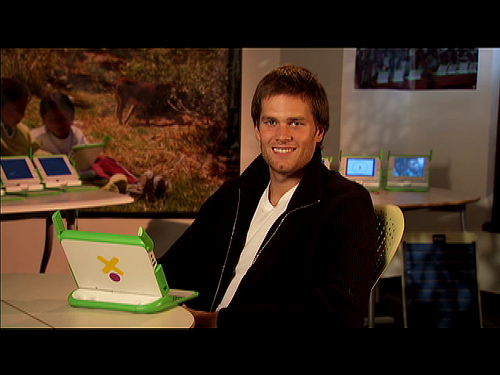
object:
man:
[162, 66, 372, 375]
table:
[0, 218, 197, 334]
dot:
[109, 273, 121, 281]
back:
[65, 237, 161, 294]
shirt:
[208, 182, 302, 310]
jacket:
[157, 148, 375, 373]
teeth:
[273, 148, 293, 153]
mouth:
[272, 144, 297, 155]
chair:
[368, 203, 406, 309]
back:
[372, 200, 405, 323]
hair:
[251, 65, 331, 122]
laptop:
[0, 151, 38, 197]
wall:
[3, 44, 343, 217]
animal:
[110, 77, 179, 119]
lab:
[0, 50, 500, 374]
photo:
[354, 40, 478, 89]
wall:
[337, 39, 499, 144]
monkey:
[418, 49, 441, 88]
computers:
[382, 151, 431, 192]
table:
[363, 190, 478, 203]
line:
[0, 278, 54, 327]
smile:
[269, 143, 300, 153]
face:
[259, 94, 313, 174]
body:
[161, 167, 371, 371]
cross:
[96, 255, 124, 271]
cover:
[73, 241, 154, 296]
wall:
[242, 49, 337, 165]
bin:
[404, 240, 484, 326]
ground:
[367, 280, 499, 374]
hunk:
[2, 286, 203, 330]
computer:
[54, 215, 197, 314]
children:
[0, 81, 80, 154]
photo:
[4, 48, 240, 214]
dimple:
[281, 162, 285, 169]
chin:
[268, 154, 297, 173]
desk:
[0, 211, 194, 328]